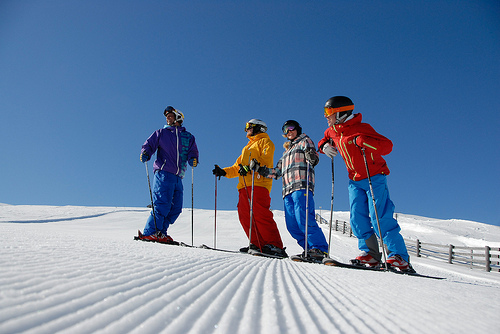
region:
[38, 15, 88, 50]
white clouds in blue sky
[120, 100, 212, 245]
skier on snowy hill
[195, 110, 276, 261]
skier on snowy hill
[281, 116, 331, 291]
skier on snowy hill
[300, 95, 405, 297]
skier on snowy hill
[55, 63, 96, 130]
white clouds in blue sky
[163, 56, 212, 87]
white clouds in blue sky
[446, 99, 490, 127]
white clouds in blue sky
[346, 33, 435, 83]
white clouds in blue sky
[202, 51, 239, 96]
white clouds in blue sky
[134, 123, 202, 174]
purple ski jacket with blue lettering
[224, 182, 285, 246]
bright red baggy ski pants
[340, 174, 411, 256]
bright blue baggy ski pants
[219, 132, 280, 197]
bright yellow ski jacket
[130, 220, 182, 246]
orange and white ski boots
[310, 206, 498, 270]
short grey wooden fence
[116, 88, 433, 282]
group of brightly clad skiers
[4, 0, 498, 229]
bright blue clear sky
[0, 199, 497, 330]
evenly grated white snow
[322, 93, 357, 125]
orange striped black plastic helmet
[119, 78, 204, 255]
The man is wearing skis.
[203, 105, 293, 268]
The man is wearing skis.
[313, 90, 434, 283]
The man is wearing skis.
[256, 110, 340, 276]
The woman is wearing skis.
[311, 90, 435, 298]
The man is leaning.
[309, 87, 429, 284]
The man is wearing a helmet.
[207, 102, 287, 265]
The man is wearing a helmet.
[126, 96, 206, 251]
The man is wearing a helmet.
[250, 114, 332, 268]
The woman is wearing a helmet.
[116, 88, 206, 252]
The man is wearing snow pants.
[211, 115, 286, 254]
A person in a yellow coat and red pants.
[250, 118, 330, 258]
A blonde girl in a plaid coat and blue pants.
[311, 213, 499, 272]
A long grey wood fence.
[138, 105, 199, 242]
A blue pants man with a purple jacket on.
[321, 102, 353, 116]
Orange goggles on a man's face.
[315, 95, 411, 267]
A man in a red coat with blue pants and orange goggles.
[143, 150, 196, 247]
Dark and light colored ski poles in the hands of a man in a purple jacket.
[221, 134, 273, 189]
Yellow coat on a man.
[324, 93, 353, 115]
Black helmet on a man with orange goggles.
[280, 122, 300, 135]
Black and clear goggles on a blonde woman's face.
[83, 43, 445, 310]
four people skiing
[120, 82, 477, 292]
four people holding ski poles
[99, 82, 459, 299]
four people standing on snow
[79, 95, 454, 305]
four people standing on white snow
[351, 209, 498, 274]
a wooden fence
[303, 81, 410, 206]
a person wearing orange goggles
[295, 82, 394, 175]
a person wearing a black helmet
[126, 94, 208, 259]
a person wearing blue ski pants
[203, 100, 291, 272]
a person wearing red snow pants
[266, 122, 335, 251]
a person wearing a plaid jacket